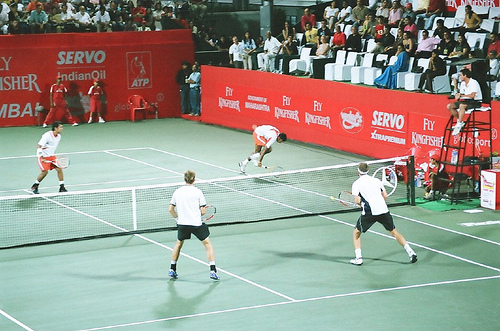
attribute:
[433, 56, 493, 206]
chair — tall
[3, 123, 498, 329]
tennis court — green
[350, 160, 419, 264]
man — black haired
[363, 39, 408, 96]
woman — sitting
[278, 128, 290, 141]
hair — black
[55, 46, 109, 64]
word — large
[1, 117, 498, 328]
court — green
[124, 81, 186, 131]
chair — empty, red, plastic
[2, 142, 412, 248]
tennis net — white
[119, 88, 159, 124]
red chair — empty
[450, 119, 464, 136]
shoe — white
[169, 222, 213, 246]
shorts — black